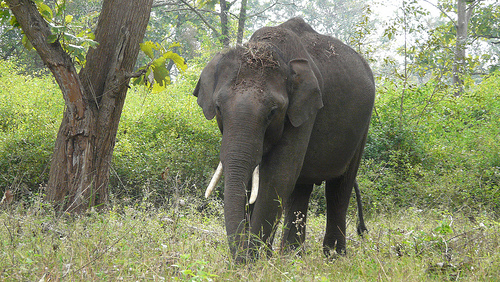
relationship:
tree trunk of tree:
[49, 1, 153, 214] [0, 1, 188, 216]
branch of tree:
[7, 0, 87, 107] [0, 1, 188, 216]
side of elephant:
[319, 68, 370, 168] [192, 14, 375, 265]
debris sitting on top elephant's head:
[239, 37, 276, 78] [193, 41, 325, 270]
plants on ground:
[4, 199, 223, 279] [8, 185, 498, 280]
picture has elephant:
[2, 3, 491, 280] [192, 14, 375, 265]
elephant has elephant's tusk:
[192, 14, 375, 265] [203, 160, 261, 206]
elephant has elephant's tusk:
[189, 15, 379, 265] [203, 160, 261, 206]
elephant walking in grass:
[192, 14, 375, 265] [43, 190, 442, 278]